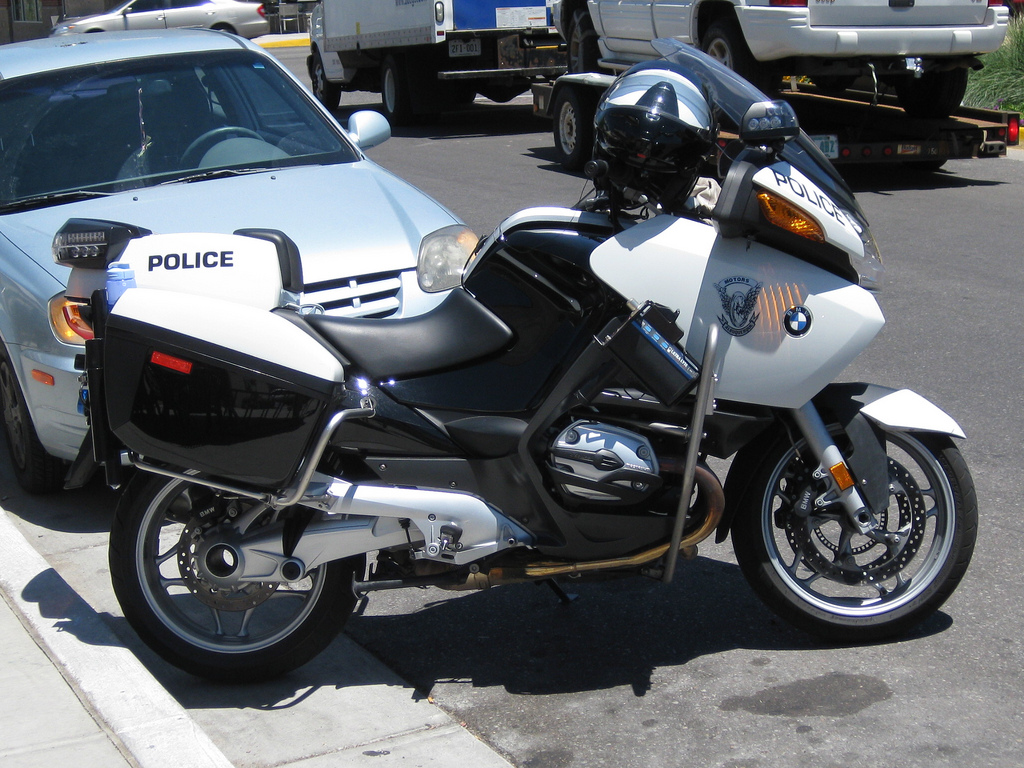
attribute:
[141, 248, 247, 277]
text — black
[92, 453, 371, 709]
tire — black